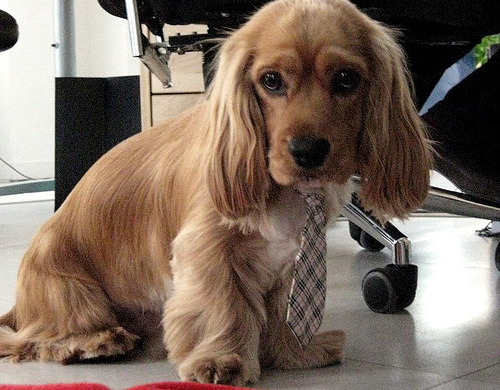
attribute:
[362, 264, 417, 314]
foot — black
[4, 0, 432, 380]
dog hair — long, tan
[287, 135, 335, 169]
nose — black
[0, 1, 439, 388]
dog — tan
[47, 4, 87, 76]
pole — metal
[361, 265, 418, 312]
wheel — black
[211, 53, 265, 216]
hair — long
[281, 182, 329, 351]
tie — plaid